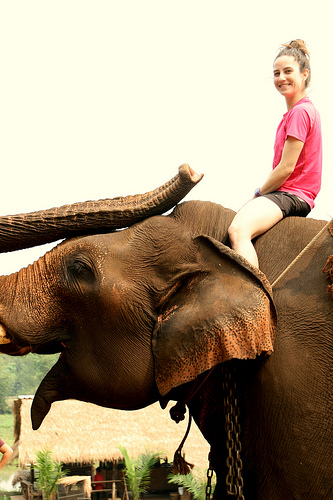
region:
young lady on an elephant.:
[3, 36, 328, 495]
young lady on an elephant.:
[3, 36, 331, 491]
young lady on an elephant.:
[8, 36, 329, 493]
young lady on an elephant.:
[1, 40, 323, 490]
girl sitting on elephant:
[246, 30, 325, 258]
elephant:
[0, 165, 230, 406]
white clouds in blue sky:
[2, 50, 55, 97]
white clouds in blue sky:
[76, 63, 121, 111]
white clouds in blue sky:
[83, 143, 117, 173]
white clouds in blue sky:
[33, 96, 83, 148]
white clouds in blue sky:
[132, 65, 176, 108]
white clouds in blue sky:
[104, 61, 160, 111]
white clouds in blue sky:
[214, 49, 263, 96]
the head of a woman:
[259, 36, 316, 107]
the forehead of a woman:
[263, 51, 300, 82]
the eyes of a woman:
[263, 59, 298, 85]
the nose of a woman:
[274, 65, 295, 90]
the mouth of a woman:
[274, 75, 298, 99]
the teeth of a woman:
[268, 67, 306, 98]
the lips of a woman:
[260, 73, 317, 117]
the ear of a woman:
[282, 51, 326, 98]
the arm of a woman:
[248, 123, 309, 214]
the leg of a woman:
[199, 162, 296, 303]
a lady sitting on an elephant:
[239, 40, 322, 258]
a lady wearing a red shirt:
[251, 46, 327, 217]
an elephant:
[7, 256, 319, 468]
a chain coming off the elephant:
[206, 381, 261, 494]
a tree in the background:
[114, 439, 161, 496]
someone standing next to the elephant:
[0, 438, 17, 468]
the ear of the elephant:
[150, 231, 264, 385]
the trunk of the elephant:
[2, 164, 203, 236]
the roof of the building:
[13, 402, 187, 462]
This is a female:
[228, 34, 325, 269]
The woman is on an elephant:
[232, 36, 326, 270]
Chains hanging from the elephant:
[177, 364, 255, 491]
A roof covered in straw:
[19, 406, 188, 462]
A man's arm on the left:
[0, 436, 15, 467]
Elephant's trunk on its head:
[11, 162, 211, 249]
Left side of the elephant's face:
[13, 200, 244, 426]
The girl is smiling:
[264, 40, 310, 99]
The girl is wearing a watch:
[249, 178, 263, 195]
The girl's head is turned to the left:
[269, 33, 313, 104]